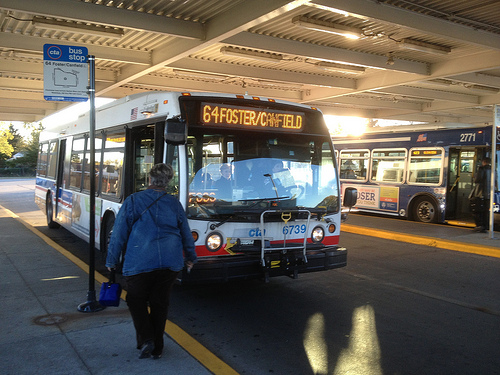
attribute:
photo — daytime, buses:
[3, 1, 500, 374]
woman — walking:
[98, 154, 201, 360]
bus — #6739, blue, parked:
[38, 89, 360, 273]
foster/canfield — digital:
[203, 102, 309, 133]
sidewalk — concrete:
[7, 209, 186, 373]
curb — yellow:
[18, 219, 230, 375]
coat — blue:
[110, 186, 193, 272]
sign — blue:
[39, 43, 92, 103]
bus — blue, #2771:
[334, 134, 499, 225]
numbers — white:
[458, 131, 480, 143]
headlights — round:
[308, 220, 329, 246]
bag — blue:
[97, 276, 122, 306]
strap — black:
[135, 194, 170, 210]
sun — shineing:
[342, 114, 378, 138]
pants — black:
[126, 266, 171, 349]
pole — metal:
[86, 52, 100, 312]